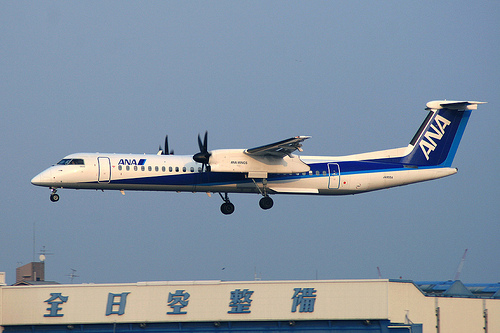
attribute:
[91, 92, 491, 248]
plane — large, flying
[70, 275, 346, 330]
letters — asian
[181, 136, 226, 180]
propeller — black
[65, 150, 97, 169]
window — cockpit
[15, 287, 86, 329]
letter — asian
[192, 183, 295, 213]
landing gear — down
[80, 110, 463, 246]
plane — white, blue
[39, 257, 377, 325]
letters — blue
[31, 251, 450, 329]
building — below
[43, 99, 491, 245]
plane — above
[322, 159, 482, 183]
door — Back 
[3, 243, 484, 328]
building — over 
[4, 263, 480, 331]
building — white , Blue  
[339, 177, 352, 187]
spot — Red 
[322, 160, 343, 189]
door — back, airplane 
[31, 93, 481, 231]
airplane — blue, white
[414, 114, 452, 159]
logo — ANA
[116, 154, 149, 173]
logo — ANA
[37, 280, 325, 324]
language — Blue written foreign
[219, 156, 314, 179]
walls — Clean crisp white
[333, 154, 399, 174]
walls — metal , Blue 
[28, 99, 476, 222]
plane — ANA airline 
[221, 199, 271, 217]
wheels — Small steady black 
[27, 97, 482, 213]
plane exterior — Front streamlined 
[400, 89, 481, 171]
tail —  white colored ,  Blue 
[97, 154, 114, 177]
door — closed plane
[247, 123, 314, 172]
wing — Big steady plane 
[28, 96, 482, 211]
plane — blue , white  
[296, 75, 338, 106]
clouds — white 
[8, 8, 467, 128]
sky — blue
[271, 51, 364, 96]
clouds — white 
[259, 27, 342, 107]
clouds — white 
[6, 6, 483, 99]
sky — blue